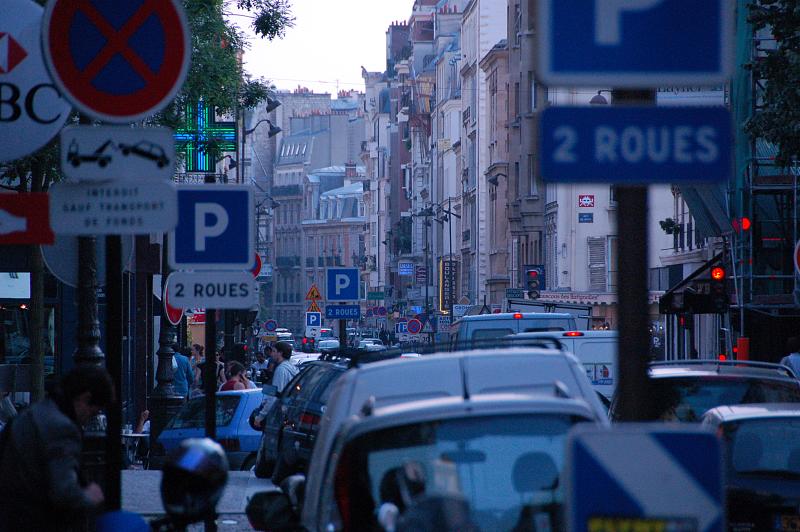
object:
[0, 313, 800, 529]
traffic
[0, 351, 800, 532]
busy street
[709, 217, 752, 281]
traffic light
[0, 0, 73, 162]
sign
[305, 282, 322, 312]
hazard sign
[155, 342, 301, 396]
people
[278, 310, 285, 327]
window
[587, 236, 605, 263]
window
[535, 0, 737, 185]
blue sign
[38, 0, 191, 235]
car sign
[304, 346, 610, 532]
white van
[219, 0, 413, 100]
sky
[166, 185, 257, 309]
street sign